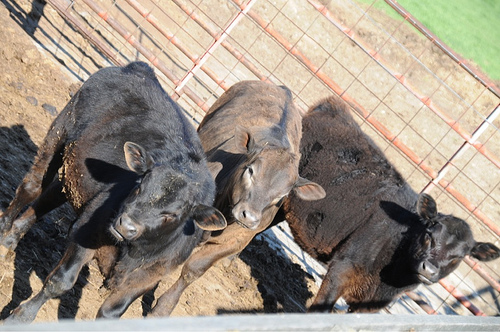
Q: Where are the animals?
A: In the pen.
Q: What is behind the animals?
A: A fence.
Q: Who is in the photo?
A: Nobody.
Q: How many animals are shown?
A: Three.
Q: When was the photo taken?
A: Daytime.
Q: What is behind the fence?
A: Dirt.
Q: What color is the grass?
A: Green.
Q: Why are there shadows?
A: The sun is shining.